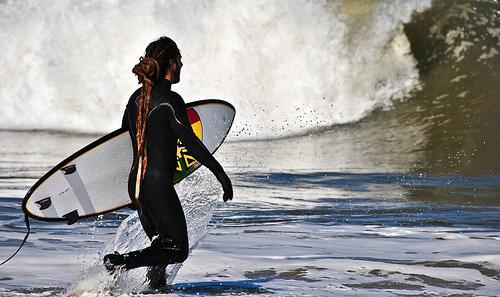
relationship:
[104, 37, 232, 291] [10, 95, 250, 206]
man holding surf board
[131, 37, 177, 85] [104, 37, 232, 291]
head belonging to man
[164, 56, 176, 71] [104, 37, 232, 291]
ear on man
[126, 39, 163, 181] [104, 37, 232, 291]
dreadlocks on man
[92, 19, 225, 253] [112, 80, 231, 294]
man in wet suit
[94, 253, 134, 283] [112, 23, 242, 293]
foot on man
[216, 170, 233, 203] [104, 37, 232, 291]
hand on man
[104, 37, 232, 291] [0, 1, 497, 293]
man splashing water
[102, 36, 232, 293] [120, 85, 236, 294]
surfer wearing wet suit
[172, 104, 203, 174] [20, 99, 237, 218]
design on surfboard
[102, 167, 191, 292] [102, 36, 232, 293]
legs on surfer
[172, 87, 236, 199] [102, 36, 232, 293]
arm on surfer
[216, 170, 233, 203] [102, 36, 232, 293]
hand on surfer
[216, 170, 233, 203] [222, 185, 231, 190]
hand has part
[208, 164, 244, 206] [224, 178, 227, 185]
hand has part